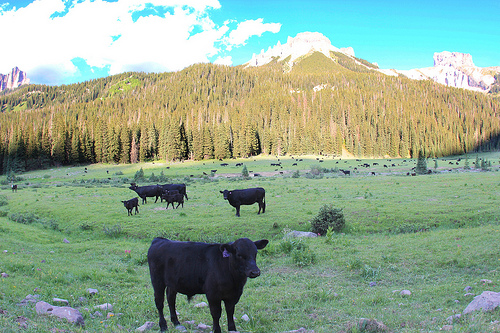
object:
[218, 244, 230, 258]
ear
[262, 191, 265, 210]
tail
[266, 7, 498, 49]
sky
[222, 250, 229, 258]
tag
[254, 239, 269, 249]
ear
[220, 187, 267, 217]
body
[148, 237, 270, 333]
black cattle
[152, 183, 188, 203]
cow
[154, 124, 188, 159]
trees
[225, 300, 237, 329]
leg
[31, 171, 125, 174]
lake water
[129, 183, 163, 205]
cows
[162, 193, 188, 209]
black cow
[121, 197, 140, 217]
cow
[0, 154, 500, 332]
field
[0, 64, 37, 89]
rock cluster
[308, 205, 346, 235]
bush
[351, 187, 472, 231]
grass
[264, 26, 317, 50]
snow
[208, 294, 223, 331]
leg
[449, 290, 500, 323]
rock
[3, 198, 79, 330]
meadow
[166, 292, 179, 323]
leg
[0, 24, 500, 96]
distance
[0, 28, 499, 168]
mountain top